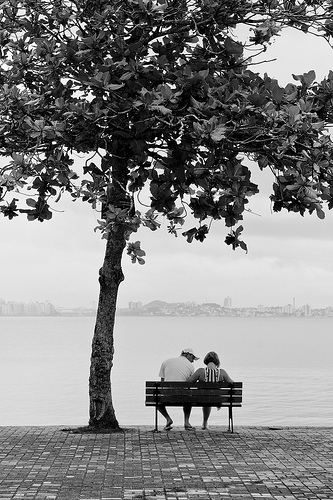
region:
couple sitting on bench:
[148, 341, 248, 417]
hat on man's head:
[180, 343, 203, 369]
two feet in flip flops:
[161, 417, 199, 436]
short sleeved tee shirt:
[154, 354, 193, 388]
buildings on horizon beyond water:
[266, 298, 317, 321]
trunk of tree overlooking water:
[81, 329, 127, 432]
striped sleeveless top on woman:
[198, 366, 225, 385]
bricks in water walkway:
[59, 447, 166, 487]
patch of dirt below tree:
[60, 422, 138, 440]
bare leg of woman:
[194, 406, 219, 429]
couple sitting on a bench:
[136, 342, 249, 432]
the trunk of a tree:
[78, 238, 135, 439]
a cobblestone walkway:
[0, 437, 331, 498]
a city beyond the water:
[162, 294, 330, 316]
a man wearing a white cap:
[155, 347, 195, 380]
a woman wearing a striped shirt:
[196, 352, 230, 381]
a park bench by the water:
[142, 380, 247, 430]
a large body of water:
[123, 321, 325, 351]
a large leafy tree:
[0, 1, 331, 234]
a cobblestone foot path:
[0, 430, 329, 499]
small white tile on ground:
[168, 473, 190, 480]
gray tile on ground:
[70, 475, 102, 488]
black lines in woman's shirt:
[203, 368, 225, 385]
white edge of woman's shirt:
[198, 366, 211, 381]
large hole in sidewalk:
[54, 420, 144, 445]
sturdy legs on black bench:
[221, 420, 255, 441]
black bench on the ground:
[132, 375, 254, 436]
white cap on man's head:
[170, 339, 199, 357]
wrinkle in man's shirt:
[176, 365, 208, 388]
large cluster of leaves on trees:
[125, 242, 161, 268]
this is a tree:
[73, 20, 176, 324]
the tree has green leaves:
[171, 139, 255, 224]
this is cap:
[183, 346, 196, 356]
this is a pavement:
[144, 433, 278, 498]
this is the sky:
[260, 213, 310, 263]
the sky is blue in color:
[258, 221, 280, 230]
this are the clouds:
[178, 262, 236, 284]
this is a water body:
[259, 319, 322, 409]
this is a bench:
[144, 381, 240, 436]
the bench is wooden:
[153, 383, 190, 400]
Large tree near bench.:
[71, 322, 182, 464]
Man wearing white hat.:
[181, 345, 202, 378]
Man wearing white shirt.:
[167, 353, 195, 398]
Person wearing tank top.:
[200, 366, 233, 408]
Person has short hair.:
[202, 343, 239, 401]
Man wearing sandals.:
[153, 417, 214, 442]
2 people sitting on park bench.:
[153, 340, 252, 447]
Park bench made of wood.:
[134, 377, 251, 410]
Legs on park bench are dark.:
[139, 397, 248, 446]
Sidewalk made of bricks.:
[117, 440, 289, 489]